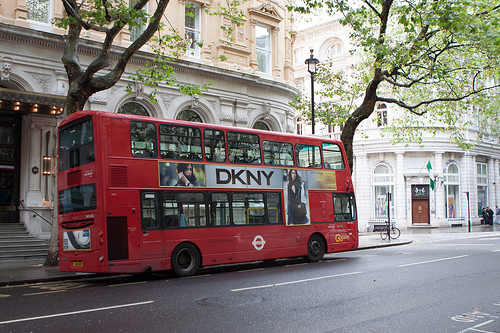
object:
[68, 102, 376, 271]
bus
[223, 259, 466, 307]
road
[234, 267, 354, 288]
line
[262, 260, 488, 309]
road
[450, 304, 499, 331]
writing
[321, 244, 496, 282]
road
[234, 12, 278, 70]
window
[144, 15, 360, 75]
building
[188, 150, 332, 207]
sign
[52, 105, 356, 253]
bus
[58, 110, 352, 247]
bus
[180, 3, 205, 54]
window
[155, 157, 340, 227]
sign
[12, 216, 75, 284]
steps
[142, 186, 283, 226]
window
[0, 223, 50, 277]
stairs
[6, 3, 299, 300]
building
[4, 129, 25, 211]
door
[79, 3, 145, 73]
limb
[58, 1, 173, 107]
tree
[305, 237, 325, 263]
wheel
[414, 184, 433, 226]
door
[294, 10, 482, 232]
building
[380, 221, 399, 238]
bicycle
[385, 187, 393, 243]
sign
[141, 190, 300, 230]
window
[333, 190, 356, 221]
window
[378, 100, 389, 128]
window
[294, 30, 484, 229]
building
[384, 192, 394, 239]
pole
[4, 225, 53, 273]
steps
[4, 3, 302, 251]
building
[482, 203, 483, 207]
people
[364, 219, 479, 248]
street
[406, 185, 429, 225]
door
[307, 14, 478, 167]
tree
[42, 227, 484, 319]
street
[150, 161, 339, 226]
advertisement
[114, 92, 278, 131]
arches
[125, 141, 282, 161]
windows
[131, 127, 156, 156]
window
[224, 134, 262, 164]
window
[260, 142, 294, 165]
window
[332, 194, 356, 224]
window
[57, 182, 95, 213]
window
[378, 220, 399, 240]
bike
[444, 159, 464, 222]
window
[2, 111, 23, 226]
door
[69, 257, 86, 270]
plate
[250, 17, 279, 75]
window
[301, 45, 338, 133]
lamp post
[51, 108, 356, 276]
bus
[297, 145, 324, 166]
window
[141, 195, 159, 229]
glass window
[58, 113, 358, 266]
bus